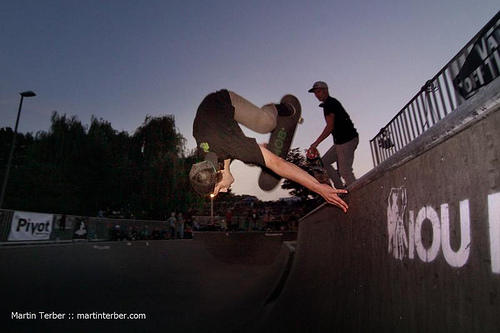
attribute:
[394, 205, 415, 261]
letters — white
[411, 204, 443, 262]
letters — white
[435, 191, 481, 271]
letters — white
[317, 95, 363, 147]
shirt — black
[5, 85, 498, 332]
ramps — cement, skateboard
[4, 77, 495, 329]
park — skate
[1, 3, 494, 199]
sky — clear, blue